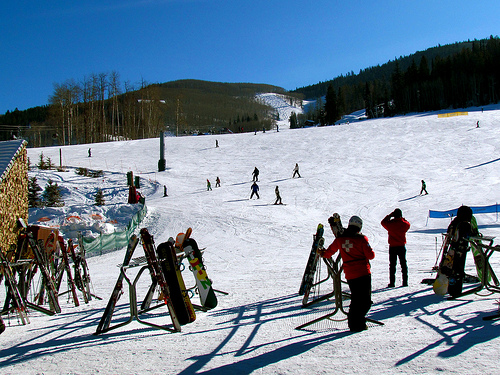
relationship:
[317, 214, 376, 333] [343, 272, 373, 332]
person has pants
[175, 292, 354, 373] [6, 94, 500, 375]
long shadow on snow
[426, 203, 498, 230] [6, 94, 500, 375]
banner on snow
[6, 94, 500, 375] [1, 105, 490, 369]
snow on ground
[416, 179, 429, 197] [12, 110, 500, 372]
person on ski slope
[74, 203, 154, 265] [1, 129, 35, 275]
wall near building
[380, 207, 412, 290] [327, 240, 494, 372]
person on ski slope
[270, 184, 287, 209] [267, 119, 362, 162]
person on slope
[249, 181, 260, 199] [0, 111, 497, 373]
person on ski slope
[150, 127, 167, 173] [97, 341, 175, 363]
pole in snow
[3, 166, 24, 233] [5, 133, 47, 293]
wall in building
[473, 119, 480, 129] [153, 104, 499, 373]
person on ski slope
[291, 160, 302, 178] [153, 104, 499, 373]
person on ski slope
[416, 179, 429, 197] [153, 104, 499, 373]
person on ski slope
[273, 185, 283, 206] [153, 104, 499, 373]
person on ski slope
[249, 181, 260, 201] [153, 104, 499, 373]
person on ski slope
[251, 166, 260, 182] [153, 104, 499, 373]
person on ski slope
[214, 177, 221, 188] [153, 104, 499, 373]
person on ski slope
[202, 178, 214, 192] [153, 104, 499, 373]
person on ski slope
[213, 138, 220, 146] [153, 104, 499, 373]
person on ski slope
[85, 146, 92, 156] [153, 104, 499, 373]
person on ski slope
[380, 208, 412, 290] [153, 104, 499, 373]
person on ski slope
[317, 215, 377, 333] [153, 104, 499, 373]
person on ski slope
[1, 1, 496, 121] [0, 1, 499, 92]
sky has no cloud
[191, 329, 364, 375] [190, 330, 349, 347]
long shadow on snow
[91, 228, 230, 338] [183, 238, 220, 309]
rack of snowboard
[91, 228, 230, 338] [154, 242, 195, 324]
rack of snowboard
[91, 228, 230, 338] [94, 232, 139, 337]
rack of skis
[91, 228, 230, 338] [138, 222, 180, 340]
rack of skis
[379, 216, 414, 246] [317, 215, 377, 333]
jacket on person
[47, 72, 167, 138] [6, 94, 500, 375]
trees on snow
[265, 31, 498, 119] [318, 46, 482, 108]
evergreen trees on mountain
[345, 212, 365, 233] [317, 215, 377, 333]
hat on person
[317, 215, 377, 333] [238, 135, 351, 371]
person in snow